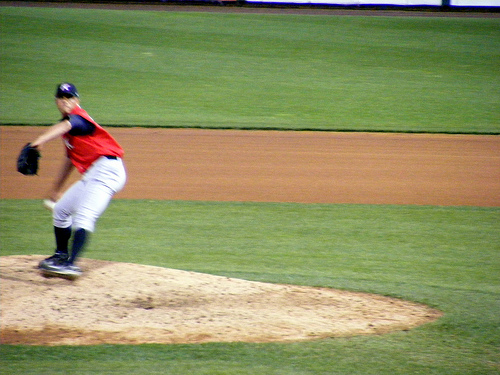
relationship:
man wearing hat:
[18, 83, 126, 280] [56, 83, 78, 98]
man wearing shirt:
[18, 83, 126, 280] [59, 108, 123, 173]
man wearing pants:
[18, 83, 126, 280] [51, 155, 127, 232]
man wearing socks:
[18, 83, 126, 280] [52, 226, 92, 262]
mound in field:
[0, 254, 283, 339] [119, 9, 500, 373]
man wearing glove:
[18, 83, 126, 280] [17, 143, 42, 178]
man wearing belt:
[18, 83, 126, 280] [105, 152, 119, 162]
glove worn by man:
[17, 143, 42, 178] [18, 83, 126, 280]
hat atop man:
[56, 83, 78, 98] [18, 83, 126, 280]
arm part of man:
[42, 157, 74, 209] [18, 83, 126, 280]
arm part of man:
[32, 117, 81, 148] [18, 83, 126, 280]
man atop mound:
[18, 83, 126, 280] [0, 254, 283, 339]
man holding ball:
[18, 83, 126, 280] [46, 197, 56, 212]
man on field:
[18, 83, 126, 280] [119, 9, 500, 373]